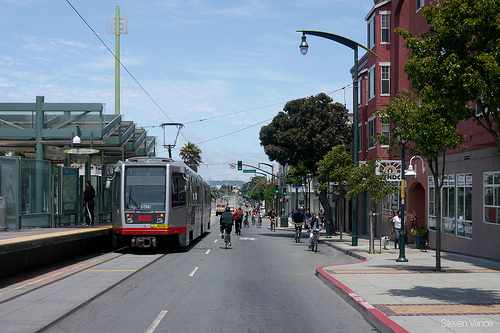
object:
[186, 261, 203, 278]
lines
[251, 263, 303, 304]
road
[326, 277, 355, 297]
curb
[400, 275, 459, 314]
sidewalk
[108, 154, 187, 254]
train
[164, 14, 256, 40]
sky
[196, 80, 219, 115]
clouds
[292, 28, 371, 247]
street lamp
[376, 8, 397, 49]
window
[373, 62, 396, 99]
window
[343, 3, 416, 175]
building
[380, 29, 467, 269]
tree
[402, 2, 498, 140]
tree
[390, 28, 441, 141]
leaves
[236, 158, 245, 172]
traffic light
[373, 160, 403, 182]
sign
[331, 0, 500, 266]
building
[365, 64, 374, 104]
window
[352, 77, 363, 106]
window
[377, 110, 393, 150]
window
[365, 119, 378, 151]
window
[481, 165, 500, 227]
window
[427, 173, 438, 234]
window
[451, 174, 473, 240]
window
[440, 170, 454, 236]
window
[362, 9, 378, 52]
window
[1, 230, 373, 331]
road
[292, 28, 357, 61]
streetlight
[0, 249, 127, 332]
tracks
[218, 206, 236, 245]
man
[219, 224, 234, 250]
bicycle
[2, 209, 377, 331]
street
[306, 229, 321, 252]
bicycle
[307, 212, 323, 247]
man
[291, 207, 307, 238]
man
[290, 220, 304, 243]
bicycle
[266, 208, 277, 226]
man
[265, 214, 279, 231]
bicycle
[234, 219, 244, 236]
bicycle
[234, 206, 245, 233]
man